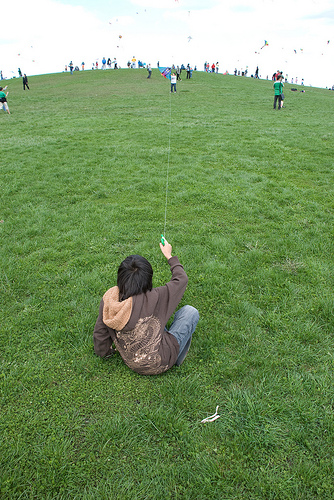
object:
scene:
[0, 1, 330, 494]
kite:
[255, 40, 269, 56]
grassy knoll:
[6, 68, 325, 205]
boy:
[92, 236, 199, 373]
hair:
[117, 256, 153, 297]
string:
[163, 144, 170, 226]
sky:
[110, 0, 232, 41]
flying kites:
[187, 35, 192, 43]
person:
[272, 78, 284, 111]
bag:
[280, 93, 285, 100]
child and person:
[186, 64, 193, 78]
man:
[0, 86, 12, 117]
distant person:
[132, 56, 137, 69]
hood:
[101, 286, 133, 334]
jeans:
[171, 304, 200, 363]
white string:
[215, 405, 218, 414]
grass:
[27, 448, 53, 489]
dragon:
[119, 314, 168, 376]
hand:
[158, 234, 172, 257]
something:
[161, 235, 165, 246]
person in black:
[22, 74, 30, 91]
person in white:
[170, 72, 177, 93]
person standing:
[255, 66, 260, 79]